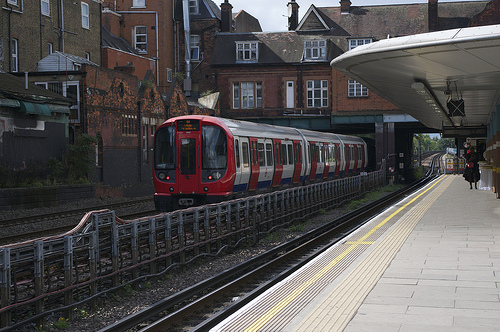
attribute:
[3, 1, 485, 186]
buildings — multi-story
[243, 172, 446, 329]
line — yellow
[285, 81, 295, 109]
door — narrow, white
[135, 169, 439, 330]
track — train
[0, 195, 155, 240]
track — train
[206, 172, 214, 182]
headlight — red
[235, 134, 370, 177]
doors — white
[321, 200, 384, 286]
line — yellow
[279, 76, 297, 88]
window — black